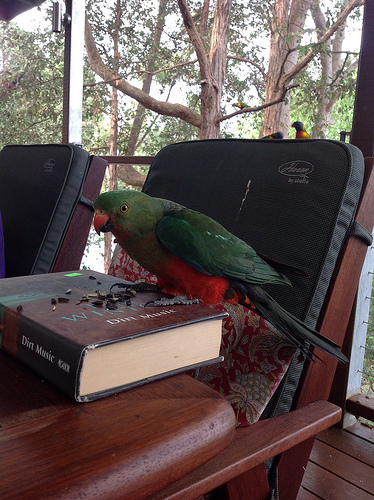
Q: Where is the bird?
A: On book.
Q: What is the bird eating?
A: Seeds.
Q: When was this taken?
A: Daytime.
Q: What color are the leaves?
A: Green.